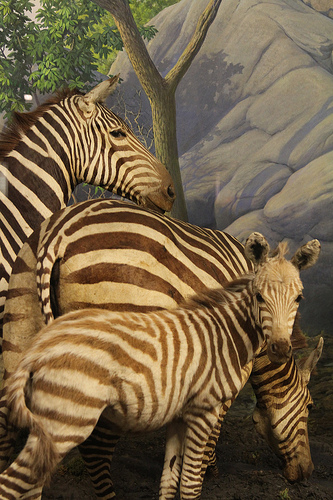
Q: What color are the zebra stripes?
A: Black.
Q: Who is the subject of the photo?
A: The zebras.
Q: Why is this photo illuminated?
A: Sunlight.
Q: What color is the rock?
A: Gray.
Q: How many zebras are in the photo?
A: 3.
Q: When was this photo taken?
A: During the day.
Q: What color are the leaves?
A: Green.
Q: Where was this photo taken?
A: At the zoo.